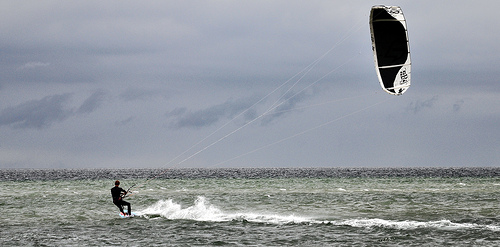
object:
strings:
[138, 19, 370, 183]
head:
[114, 180, 120, 186]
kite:
[368, 5, 412, 97]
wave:
[222, 212, 307, 225]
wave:
[131, 197, 180, 218]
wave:
[419, 218, 500, 232]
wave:
[344, 216, 404, 230]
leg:
[115, 204, 126, 217]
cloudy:
[256, 86, 308, 129]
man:
[110, 180, 132, 216]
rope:
[136, 95, 396, 192]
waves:
[170, 194, 226, 221]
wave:
[242, 185, 269, 196]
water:
[0, 167, 497, 247]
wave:
[229, 210, 307, 223]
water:
[81, 189, 233, 230]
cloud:
[2, 87, 74, 132]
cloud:
[158, 89, 263, 132]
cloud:
[403, 93, 447, 116]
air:
[0, 0, 499, 169]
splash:
[167, 195, 231, 222]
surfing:
[116, 205, 156, 221]